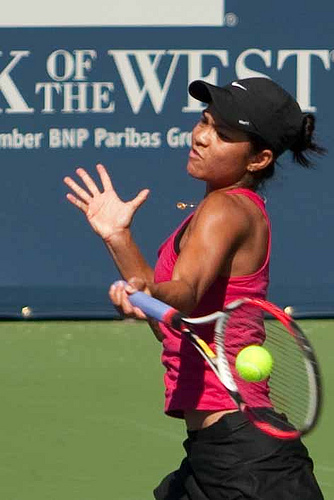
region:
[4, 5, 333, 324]
Blue banner in background.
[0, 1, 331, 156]
Banner advertising Bank of West.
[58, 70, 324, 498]
Woman is playing tennis.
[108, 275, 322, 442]
Woman holding tennis racquet.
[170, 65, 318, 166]
Woman is wearing black cap.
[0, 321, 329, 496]
Tennis court surface is green.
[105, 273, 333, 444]
Tennis ball about to connect with racquet.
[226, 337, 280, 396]
Tennis ball is yellow.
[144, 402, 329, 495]
Woman wearing black skort.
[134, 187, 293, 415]
Woman's shirt is bright red.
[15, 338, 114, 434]
Green surface of the tennis court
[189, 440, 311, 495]
Player's black shorts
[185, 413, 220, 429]
Player's stomach between her shirt and her shorts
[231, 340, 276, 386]
Yellow tennis ball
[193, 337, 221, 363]
Yellow portion of the middle of the tennis racket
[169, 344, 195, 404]
Front of the player's pink shirt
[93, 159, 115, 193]
Player's right index finger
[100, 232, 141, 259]
Payer's right wrist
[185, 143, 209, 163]
Player's mouth set firmly in concentration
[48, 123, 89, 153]
White BNP on the blue wall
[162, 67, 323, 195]
a grimace from an athlete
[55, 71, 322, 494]
a player in a pink shirt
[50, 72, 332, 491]
a player sponsored by Nike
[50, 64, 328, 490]
a left handed forehand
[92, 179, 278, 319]
lean muscle in action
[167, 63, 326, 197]
a hairdo for daytime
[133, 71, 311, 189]
eyes focused on desired target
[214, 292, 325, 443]
a pink, white and black racket head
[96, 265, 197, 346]
a blue racket grip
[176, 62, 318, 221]
girl wearing black hat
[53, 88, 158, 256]
open palm of right hand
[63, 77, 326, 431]
player awkwardly hitting tennis ball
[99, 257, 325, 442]
tennis racket held in left hand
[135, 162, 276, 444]
red sleeveless top pulling up to reveal midriff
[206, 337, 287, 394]
green ball on crossed tennis strings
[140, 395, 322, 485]
black skirt wrinkling in response to player's moves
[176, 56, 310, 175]
black cap with white logo in front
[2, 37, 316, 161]
advertisement of white letters against blue background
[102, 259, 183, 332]
hand curled around the neck of the tennis racket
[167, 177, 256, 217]
necklace pendant flying in the air horizontally from chain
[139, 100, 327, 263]
The woman wears a gold necklace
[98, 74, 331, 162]
The woman wears a black hat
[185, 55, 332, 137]
The white swoosh indicates Nike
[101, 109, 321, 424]
The woman is playing tennis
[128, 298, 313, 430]
The ball is lime green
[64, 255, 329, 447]
A tennis racket is used to play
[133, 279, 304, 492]
The woman wears a tank top and skirt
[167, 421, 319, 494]
The skirt is black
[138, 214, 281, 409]
The tank top is magenta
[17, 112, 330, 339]
The background is blue